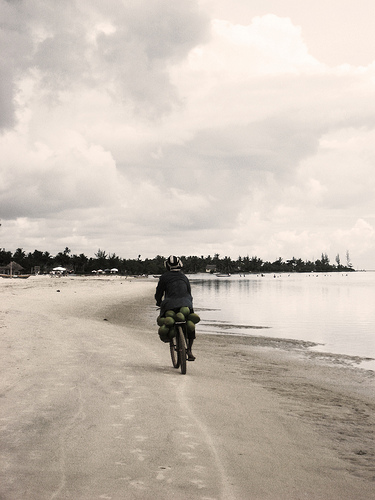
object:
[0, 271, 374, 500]
sand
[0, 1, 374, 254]
sky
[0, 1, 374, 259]
clouds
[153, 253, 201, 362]
man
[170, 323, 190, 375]
bike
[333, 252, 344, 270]
trees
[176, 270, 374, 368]
water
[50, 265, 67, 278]
house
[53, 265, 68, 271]
roof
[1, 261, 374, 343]
beach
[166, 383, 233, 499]
track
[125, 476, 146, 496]
footprints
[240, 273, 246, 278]
people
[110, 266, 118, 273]
umbrella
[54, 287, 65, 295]
object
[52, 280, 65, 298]
spot